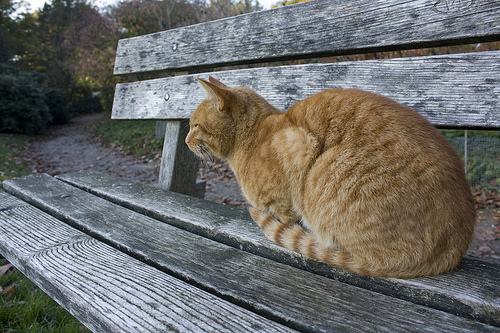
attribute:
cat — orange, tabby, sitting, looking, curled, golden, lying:
[172, 68, 474, 283]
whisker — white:
[193, 142, 217, 157]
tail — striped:
[249, 205, 329, 260]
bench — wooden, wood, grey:
[54, 31, 210, 308]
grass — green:
[7, 283, 47, 328]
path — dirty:
[52, 119, 109, 167]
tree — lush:
[25, 15, 110, 100]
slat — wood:
[114, 34, 194, 66]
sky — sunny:
[27, 1, 45, 14]